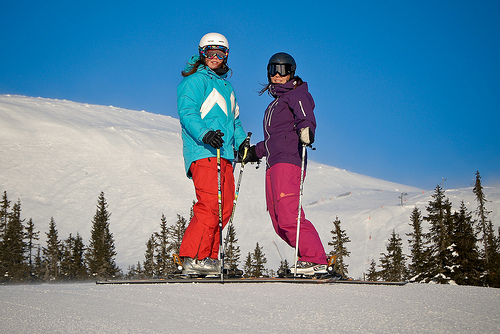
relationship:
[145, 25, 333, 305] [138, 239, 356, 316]
women on ski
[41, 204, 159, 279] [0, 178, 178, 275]
tree in distance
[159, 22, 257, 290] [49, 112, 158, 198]
woman on snow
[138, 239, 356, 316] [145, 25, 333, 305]
ski under women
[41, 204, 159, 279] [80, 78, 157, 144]
tree on hill